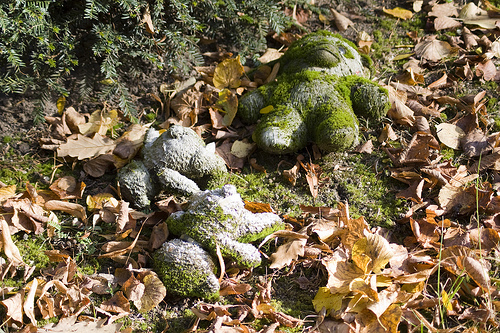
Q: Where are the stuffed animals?
A: On the ground.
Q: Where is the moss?
A: On the old stuffed animals.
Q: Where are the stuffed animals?
A: On the side of the road.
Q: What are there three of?
A: Stuffed animals.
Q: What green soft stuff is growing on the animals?
A: Moss.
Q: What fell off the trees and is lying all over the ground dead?
A: Leaves.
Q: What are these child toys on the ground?
A: Stuffed animals.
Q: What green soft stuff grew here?
A: Moss.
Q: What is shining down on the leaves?
A: Sun.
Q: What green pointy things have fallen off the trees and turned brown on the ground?
A: Leaves.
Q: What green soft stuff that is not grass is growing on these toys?
A: Moss.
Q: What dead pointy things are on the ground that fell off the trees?
A: Leaves.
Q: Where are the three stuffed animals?
A: On the ground.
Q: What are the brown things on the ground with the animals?
A: Leaves.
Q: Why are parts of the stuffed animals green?
A: Moss.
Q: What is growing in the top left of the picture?
A: Bush.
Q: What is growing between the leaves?
A: Grass and moss.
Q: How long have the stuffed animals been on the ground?
A: A long time.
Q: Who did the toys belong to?
A: Child.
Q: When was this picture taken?
A: Fall.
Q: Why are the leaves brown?
A: The leaves are dead.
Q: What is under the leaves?
A: Brown dirt.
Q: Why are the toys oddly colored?
A: Moss and snow.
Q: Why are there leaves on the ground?
A: Left from Autumn.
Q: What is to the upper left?
A: Evergreen.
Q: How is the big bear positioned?
A: Face-up.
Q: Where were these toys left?
A: Forest area.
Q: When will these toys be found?
A: Never.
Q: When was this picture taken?
A: Daytime.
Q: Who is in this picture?
A: No one.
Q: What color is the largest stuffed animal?
A: Green.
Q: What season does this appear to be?
A: Fall.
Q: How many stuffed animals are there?
A: Three.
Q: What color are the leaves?
A: Yellow and brown.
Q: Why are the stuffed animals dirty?
A: On the ground.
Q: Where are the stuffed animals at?
A: On the ground.